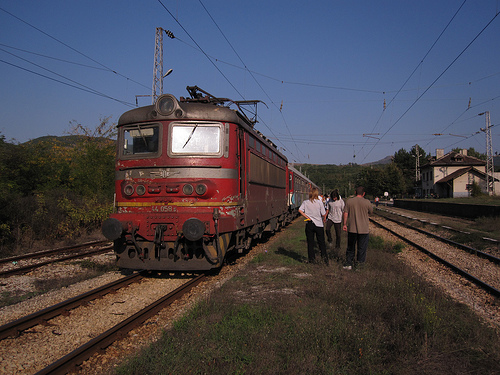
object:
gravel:
[132, 329, 140, 336]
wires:
[2, 53, 50, 76]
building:
[416, 148, 499, 198]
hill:
[2, 131, 111, 253]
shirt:
[300, 198, 323, 225]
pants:
[305, 219, 326, 261]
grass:
[120, 350, 165, 372]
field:
[2, 199, 484, 373]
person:
[320, 192, 330, 215]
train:
[97, 81, 322, 273]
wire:
[158, 0, 299, 160]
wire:
[2, 10, 154, 90]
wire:
[173, 37, 399, 95]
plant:
[52, 194, 85, 241]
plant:
[26, 198, 74, 248]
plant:
[76, 193, 105, 229]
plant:
[1, 194, 38, 223]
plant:
[2, 226, 24, 257]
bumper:
[99, 215, 122, 240]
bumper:
[180, 216, 206, 239]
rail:
[369, 210, 484, 293]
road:
[378, 201, 484, 230]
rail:
[372, 210, 482, 262]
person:
[321, 193, 329, 207]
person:
[338, 193, 346, 210]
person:
[298, 186, 333, 266]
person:
[323, 189, 345, 249]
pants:
[323, 215, 343, 248]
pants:
[342, 230, 368, 264]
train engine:
[112, 99, 292, 235]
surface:
[112, 116, 236, 239]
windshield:
[172, 126, 220, 154]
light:
[169, 123, 219, 153]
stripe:
[113, 200, 240, 209]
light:
[122, 182, 136, 194]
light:
[134, 182, 145, 194]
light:
[181, 180, 195, 194]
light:
[195, 183, 206, 195]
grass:
[60, 142, 114, 182]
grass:
[429, 320, 458, 349]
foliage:
[364, 304, 422, 349]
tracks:
[2, 271, 198, 370]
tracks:
[373, 205, 497, 301]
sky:
[1, 5, 494, 164]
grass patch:
[355, 279, 397, 314]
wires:
[352, 33, 437, 152]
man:
[341, 184, 376, 269]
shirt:
[340, 195, 375, 231]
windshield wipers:
[182, 122, 199, 148]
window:
[168, 122, 229, 160]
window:
[118, 124, 158, 159]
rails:
[40, 231, 226, 371]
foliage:
[281, 331, 314, 369]